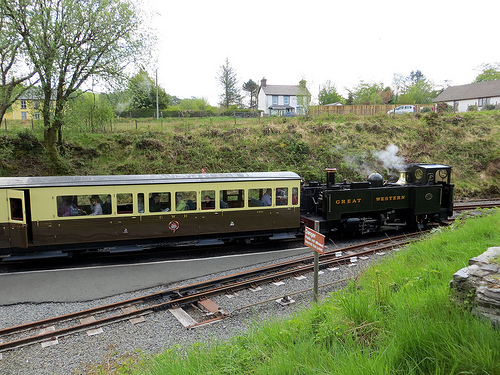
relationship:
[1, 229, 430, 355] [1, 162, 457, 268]
train tracks beside train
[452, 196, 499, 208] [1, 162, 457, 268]
train tracks beside train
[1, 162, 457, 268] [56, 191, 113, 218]
train has window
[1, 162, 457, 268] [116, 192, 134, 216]
train has window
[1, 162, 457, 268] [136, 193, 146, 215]
train has window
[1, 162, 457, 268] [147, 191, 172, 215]
train has window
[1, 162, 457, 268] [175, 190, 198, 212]
train has window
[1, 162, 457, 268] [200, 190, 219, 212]
train has window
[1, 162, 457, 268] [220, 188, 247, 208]
train has window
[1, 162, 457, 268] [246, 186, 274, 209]
train has window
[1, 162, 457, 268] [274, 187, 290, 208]
train has window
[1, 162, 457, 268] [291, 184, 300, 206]
train has window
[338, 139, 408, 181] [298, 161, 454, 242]
smoke coming from engine train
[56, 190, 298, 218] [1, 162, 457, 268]
passengers inside train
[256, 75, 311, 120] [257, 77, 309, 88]
house has two chimneys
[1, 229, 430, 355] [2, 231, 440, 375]
train tracks on gravel road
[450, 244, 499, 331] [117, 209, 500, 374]
pile of stones in grass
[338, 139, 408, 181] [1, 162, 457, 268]
smoke coming from train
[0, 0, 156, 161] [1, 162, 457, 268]
tree near train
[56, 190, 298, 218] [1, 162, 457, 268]
people on train